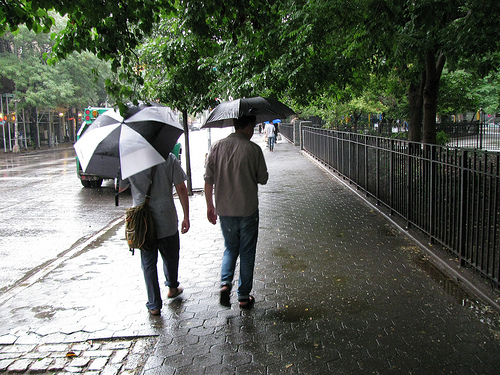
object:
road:
[0, 145, 213, 261]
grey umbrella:
[199, 96, 299, 131]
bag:
[125, 168, 158, 257]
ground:
[0, 269, 499, 375]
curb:
[6, 143, 69, 160]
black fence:
[298, 115, 499, 277]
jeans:
[218, 213, 260, 299]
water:
[75, 222, 110, 240]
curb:
[2, 207, 116, 290]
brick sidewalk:
[260, 228, 401, 373]